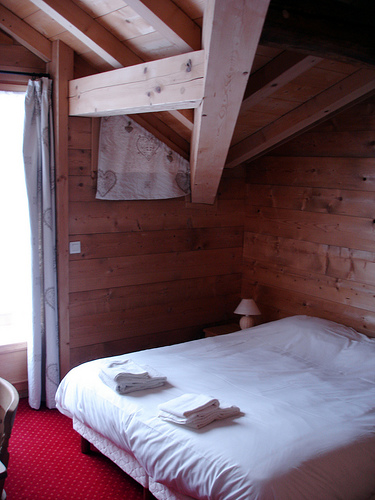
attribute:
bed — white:
[55, 314, 374, 499]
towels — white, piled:
[100, 362, 166, 393]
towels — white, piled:
[158, 392, 241, 430]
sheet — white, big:
[55, 314, 374, 499]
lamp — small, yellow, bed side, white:
[233, 298, 260, 331]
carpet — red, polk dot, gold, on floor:
[3, 397, 153, 499]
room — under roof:
[0, 1, 373, 499]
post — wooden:
[80, 436, 90, 455]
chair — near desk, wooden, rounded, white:
[0, 376, 19, 499]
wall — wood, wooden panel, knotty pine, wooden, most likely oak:
[67, 115, 244, 374]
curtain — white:
[95, 114, 193, 201]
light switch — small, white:
[70, 240, 80, 256]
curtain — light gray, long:
[23, 78, 58, 413]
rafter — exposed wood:
[0, 6, 191, 162]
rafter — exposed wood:
[30, 0, 195, 132]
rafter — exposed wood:
[126, 0, 202, 53]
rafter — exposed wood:
[239, 50, 322, 115]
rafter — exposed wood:
[224, 66, 374, 169]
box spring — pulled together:
[71, 416, 148, 489]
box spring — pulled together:
[149, 476, 181, 499]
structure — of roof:
[69, 49, 206, 119]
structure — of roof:
[190, 0, 272, 205]